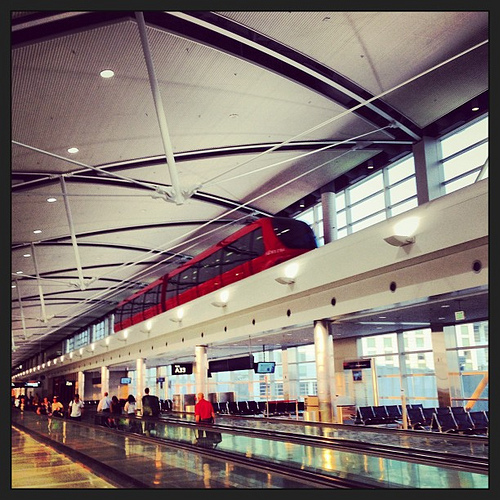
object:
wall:
[307, 230, 383, 291]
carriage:
[13, 217, 318, 375]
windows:
[399, 331, 438, 408]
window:
[384, 154, 419, 217]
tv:
[121, 375, 132, 384]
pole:
[101, 366, 110, 398]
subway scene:
[11, 12, 488, 489]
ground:
[11, 416, 489, 490]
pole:
[312, 321, 338, 423]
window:
[220, 233, 251, 274]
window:
[197, 252, 221, 283]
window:
[177, 262, 198, 295]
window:
[164, 272, 179, 300]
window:
[142, 285, 162, 311]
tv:
[352, 371, 362, 381]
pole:
[370, 358, 379, 406]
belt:
[213, 443, 217, 448]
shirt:
[195, 398, 216, 418]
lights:
[284, 262, 300, 280]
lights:
[67, 353, 77, 358]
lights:
[68, 147, 80, 153]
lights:
[99, 69, 114, 78]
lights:
[46, 196, 57, 203]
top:
[151, 185, 205, 205]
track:
[330, 475, 383, 491]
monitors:
[120, 376, 131, 384]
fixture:
[275, 277, 298, 286]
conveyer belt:
[92, 412, 231, 452]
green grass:
[46, 418, 65, 431]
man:
[195, 391, 216, 438]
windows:
[357, 336, 405, 406]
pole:
[265, 372, 268, 415]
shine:
[323, 449, 336, 472]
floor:
[9, 11, 491, 490]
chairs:
[350, 405, 491, 426]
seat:
[406, 406, 426, 431]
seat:
[467, 410, 487, 429]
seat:
[430, 406, 459, 433]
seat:
[372, 405, 389, 425]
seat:
[420, 408, 437, 424]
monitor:
[255, 362, 276, 374]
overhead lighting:
[63, 195, 131, 283]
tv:
[254, 361, 276, 374]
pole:
[195, 344, 208, 401]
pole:
[136, 359, 146, 400]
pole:
[77, 371, 84, 401]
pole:
[58, 174, 85, 291]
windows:
[347, 166, 386, 238]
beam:
[10, 6, 487, 339]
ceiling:
[11, 11, 489, 345]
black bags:
[192, 429, 197, 440]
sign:
[174, 365, 186, 373]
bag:
[204, 431, 222, 443]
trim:
[319, 148, 384, 169]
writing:
[174, 364, 186, 373]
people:
[29, 387, 161, 435]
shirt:
[69, 400, 85, 418]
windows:
[250, 228, 266, 260]